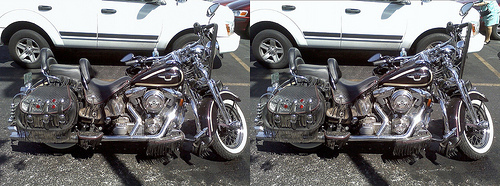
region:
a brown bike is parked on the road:
[23, 39, 251, 169]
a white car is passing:
[46, 3, 171, 43]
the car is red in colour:
[236, 1, 252, 27]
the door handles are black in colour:
[95, 6, 120, 13]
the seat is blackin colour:
[38, 44, 145, 106]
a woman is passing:
[473, 3, 495, 33]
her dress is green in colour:
[476, 2, 498, 24]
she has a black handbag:
[482, 3, 490, 17]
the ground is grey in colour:
[80, 156, 185, 176]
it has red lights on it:
[19, 93, 80, 112]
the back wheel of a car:
[261, 35, 280, 57]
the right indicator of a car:
[226, 24, 231, 34]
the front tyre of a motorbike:
[217, 143, 244, 155]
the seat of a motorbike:
[329, 60, 356, 89]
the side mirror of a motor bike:
[465, 1, 475, 14]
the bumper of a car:
[221, 39, 240, 50]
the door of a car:
[348, 9, 384, 36]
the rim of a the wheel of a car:
[262, 44, 268, 56]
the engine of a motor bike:
[129, 90, 179, 127]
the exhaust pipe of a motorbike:
[106, 136, 128, 142]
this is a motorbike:
[71, 40, 263, 182]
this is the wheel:
[215, 94, 252, 157]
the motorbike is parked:
[326, 55, 470, 170]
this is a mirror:
[458, 1, 473, 18]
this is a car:
[0, 2, 171, 47]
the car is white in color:
[116, 7, 161, 22]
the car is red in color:
[241, 6, 248, 24]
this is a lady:
[483, 2, 493, 33]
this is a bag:
[480, 6, 491, 21]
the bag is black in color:
[479, 7, 492, 17]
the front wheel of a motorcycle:
[216, 93, 246, 158]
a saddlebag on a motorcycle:
[267, 86, 330, 136]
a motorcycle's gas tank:
[140, 60, 184, 90]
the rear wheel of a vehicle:
[2, 24, 50, 68]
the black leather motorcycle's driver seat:
[80, 61, 132, 102]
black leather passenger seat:
[44, 51, 82, 83]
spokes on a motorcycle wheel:
[220, 133, 239, 143]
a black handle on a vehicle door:
[342, 1, 364, 15]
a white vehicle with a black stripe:
[257, 0, 485, 70]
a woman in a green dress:
[481, 0, 498, 47]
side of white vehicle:
[1, 1, 238, 66]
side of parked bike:
[7, 3, 247, 160]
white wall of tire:
[213, 99, 248, 154]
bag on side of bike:
[15, 85, 78, 135]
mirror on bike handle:
[204, 1, 221, 20]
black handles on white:
[279, 4, 366, 13]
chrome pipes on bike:
[103, 108, 177, 145]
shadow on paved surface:
[101, 151, 147, 184]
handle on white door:
[101, 8, 117, 16]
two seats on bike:
[39, 48, 129, 103]